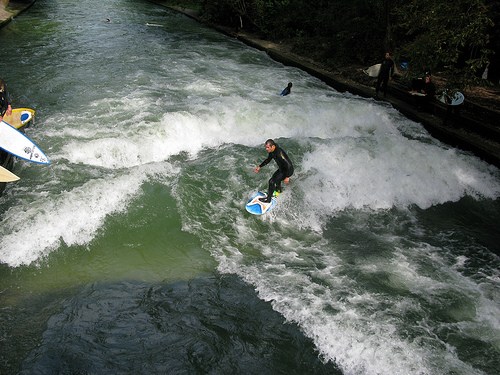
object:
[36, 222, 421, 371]
water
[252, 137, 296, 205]
man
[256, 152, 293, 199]
wetsuit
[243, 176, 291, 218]
surfboard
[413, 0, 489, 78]
trees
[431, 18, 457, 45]
leaves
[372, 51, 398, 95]
person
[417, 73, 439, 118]
person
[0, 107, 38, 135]
boat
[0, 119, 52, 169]
surfboard